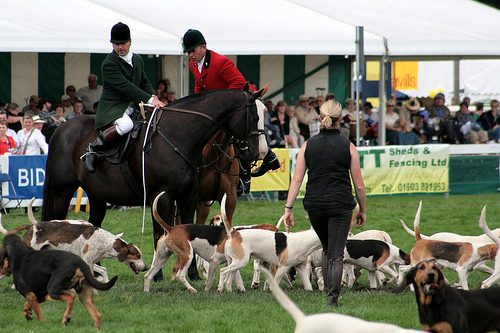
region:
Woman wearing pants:
[304, 201, 356, 303]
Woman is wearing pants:
[302, 200, 347, 300]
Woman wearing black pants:
[307, 201, 354, 300]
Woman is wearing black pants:
[303, 197, 349, 298]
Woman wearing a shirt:
[299, 126, 360, 208]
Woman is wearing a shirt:
[297, 120, 362, 210]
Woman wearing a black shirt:
[302, 124, 357, 216]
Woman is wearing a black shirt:
[299, 124, 366, 210]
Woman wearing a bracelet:
[281, 200, 295, 211]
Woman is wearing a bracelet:
[282, 200, 294, 212]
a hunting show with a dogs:
[18, 1, 498, 324]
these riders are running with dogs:
[0, 19, 273, 297]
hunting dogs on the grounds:
[2, 213, 273, 305]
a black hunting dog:
[4, 235, 123, 323]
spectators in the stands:
[280, 80, 487, 145]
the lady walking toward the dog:
[293, 89, 393, 294]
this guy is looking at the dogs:
[172, 16, 255, 129]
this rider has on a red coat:
[173, 31, 261, 101]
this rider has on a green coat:
[70, 18, 167, 119]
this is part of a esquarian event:
[18, 17, 483, 315]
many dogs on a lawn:
[0, 190, 499, 330]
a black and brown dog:
[403, 259, 495, 331]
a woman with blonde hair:
[316, 99, 342, 134]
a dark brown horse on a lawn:
[43, 88, 261, 283]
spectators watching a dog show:
[0, 73, 498, 153]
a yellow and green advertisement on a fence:
[292, 143, 452, 192]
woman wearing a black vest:
[303, 129, 355, 212]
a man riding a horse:
[82, 23, 164, 171]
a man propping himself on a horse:
[181, 28, 282, 176]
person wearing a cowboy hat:
[402, 95, 421, 110]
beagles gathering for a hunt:
[143, 212, 498, 292]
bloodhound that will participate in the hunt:
[0, 230, 120, 322]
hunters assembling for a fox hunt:
[83, 19, 253, 174]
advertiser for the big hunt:
[286, 142, 451, 196]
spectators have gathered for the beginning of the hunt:
[272, 85, 496, 144]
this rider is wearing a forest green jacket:
[88, 50, 163, 132]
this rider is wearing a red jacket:
[183, 48, 259, 97]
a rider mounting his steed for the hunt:
[176, 28, 283, 226]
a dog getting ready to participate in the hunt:
[396, 255, 498, 330]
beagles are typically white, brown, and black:
[148, 218, 282, 295]